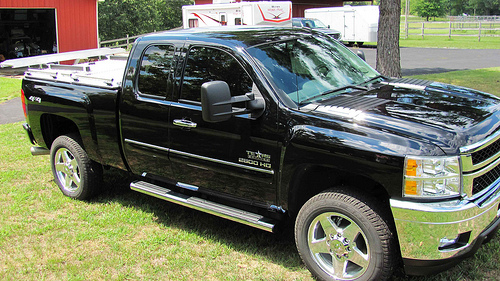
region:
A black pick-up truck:
[15, 16, 497, 277]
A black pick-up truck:
[17, 21, 490, 277]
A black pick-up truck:
[18, 12, 489, 277]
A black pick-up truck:
[15, 21, 496, 276]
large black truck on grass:
[17, 18, 495, 272]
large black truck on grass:
[24, 3, 476, 258]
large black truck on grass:
[21, 1, 498, 278]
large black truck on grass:
[21, 5, 495, 272]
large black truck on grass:
[31, 5, 491, 277]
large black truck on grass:
[28, 11, 496, 278]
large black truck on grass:
[30, 5, 497, 263]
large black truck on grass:
[20, 2, 488, 279]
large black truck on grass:
[17, 6, 478, 271]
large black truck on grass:
[34, 3, 478, 260]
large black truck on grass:
[25, 9, 466, 261]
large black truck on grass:
[22, 11, 496, 278]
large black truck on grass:
[21, 13, 488, 261]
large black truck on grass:
[20, 23, 487, 247]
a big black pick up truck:
[17, 26, 489, 271]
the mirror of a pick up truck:
[190, 75, 240, 125]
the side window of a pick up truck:
[144, 29, 236, 103]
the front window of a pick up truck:
[238, 22, 358, 107]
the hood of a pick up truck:
[352, 65, 473, 152]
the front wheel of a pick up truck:
[301, 191, 391, 276]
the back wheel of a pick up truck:
[34, 138, 82, 193]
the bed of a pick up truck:
[31, 46, 129, 100]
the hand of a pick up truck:
[148, 101, 200, 139]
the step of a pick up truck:
[168, 178, 245, 250]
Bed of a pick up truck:
[89, 60, 123, 75]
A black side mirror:
[203, 85, 228, 116]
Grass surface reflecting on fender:
[407, 213, 427, 256]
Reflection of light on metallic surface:
[402, 203, 424, 206]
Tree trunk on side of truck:
[379, 47, 397, 69]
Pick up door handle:
[175, 118, 196, 127]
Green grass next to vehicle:
[96, 217, 126, 239]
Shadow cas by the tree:
[405, 68, 421, 73]